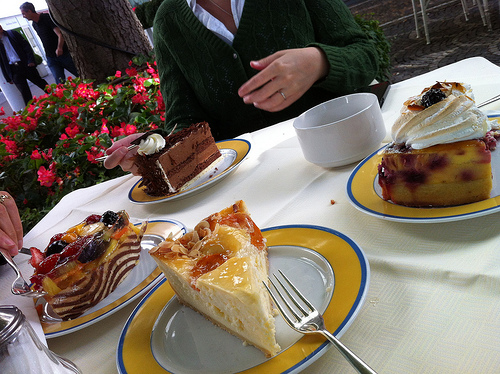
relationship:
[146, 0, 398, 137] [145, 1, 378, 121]
person wearing green shirt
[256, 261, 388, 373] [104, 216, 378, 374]
fork on plate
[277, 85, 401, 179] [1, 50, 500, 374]
coffee cup on table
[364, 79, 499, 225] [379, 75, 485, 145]
fruit cake has topping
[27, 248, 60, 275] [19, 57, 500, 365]
strawberry on tablecloth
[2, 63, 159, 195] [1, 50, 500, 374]
red flowers are beside table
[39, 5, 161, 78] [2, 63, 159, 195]
tree trunk around red flowers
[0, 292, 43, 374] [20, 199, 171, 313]
container next to dessert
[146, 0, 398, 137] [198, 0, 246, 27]
woman wearing silver necklace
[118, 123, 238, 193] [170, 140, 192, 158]
pie has caramel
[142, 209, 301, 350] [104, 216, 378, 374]
cheesecake on plate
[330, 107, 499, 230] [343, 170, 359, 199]
plate has blue trim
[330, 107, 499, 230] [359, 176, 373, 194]
plate has yellow trim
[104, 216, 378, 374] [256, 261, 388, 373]
plate has fork set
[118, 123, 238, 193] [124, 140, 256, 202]
chocolate cake on plate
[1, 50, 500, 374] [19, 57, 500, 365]
table has cloth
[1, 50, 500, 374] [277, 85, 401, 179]
table has bowl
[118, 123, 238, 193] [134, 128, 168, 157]
chocolate cake has icing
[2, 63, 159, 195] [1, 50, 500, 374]
flowers next to table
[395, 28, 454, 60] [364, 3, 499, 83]
stones are on ground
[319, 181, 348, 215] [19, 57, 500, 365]
crumb on tablecloth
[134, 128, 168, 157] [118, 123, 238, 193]
whipped cream on cake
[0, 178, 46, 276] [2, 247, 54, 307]
hand holding fork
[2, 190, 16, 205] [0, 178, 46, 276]
ring on hand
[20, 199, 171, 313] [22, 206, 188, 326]
dessert on plate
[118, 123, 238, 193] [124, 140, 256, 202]
cake on plate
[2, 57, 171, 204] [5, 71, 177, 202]
red flowers on bush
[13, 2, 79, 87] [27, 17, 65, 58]
man wearing black shirt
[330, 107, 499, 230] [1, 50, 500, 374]
plate on table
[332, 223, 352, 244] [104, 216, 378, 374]
blue trim on plate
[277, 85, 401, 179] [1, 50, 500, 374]
white cup on table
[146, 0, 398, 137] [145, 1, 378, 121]
person wearing green sweater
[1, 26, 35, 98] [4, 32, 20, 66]
person wearing white shirt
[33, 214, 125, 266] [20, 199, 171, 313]
fruit on pie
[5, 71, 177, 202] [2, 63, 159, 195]
bush has red flowers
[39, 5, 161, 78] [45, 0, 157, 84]
tree has tree trunk